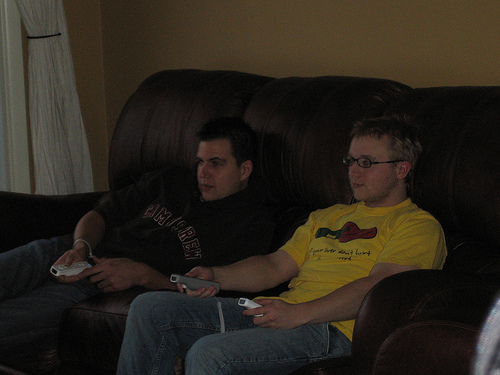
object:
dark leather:
[115, 68, 499, 154]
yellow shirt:
[251, 199, 448, 341]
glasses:
[343, 154, 405, 168]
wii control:
[50, 261, 93, 277]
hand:
[49, 261, 92, 277]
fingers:
[243, 298, 279, 331]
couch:
[0, 68, 499, 374]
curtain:
[4, 0, 96, 196]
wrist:
[286, 283, 322, 340]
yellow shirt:
[245, 190, 445, 340]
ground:
[343, 87, 410, 133]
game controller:
[169, 274, 220, 295]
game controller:
[238, 297, 264, 316]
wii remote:
[170, 274, 221, 296]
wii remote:
[49, 261, 93, 277]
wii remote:
[225, 285, 281, 321]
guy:
[117, 113, 449, 375]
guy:
[0, 120, 266, 344]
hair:
[349, 117, 421, 161]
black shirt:
[92, 164, 284, 275]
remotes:
[48, 261, 266, 318]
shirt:
[251, 198, 448, 346]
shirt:
[90, 183, 285, 293]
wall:
[309, 12, 425, 69]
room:
[4, 2, 497, 372]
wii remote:
[168, 270, 221, 295]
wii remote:
[48, 255, 94, 279]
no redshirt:
[262, 130, 448, 260]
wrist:
[135, 258, 153, 287]